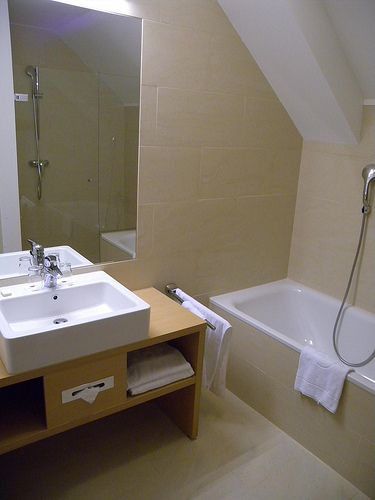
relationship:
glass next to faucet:
[18, 285, 120, 355] [20, 251, 72, 307]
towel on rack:
[173, 298, 260, 374] [166, 282, 231, 335]